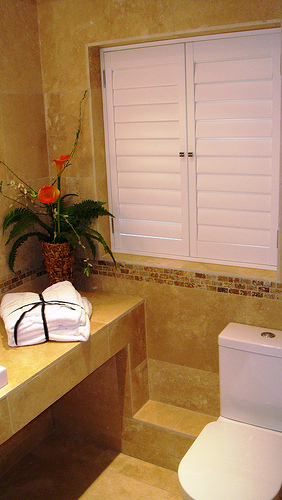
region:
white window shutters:
[95, 27, 281, 274]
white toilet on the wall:
[176, 319, 281, 499]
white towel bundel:
[1, 279, 99, 349]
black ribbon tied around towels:
[1, 280, 94, 347]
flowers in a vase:
[0, 150, 118, 300]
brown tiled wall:
[1, 0, 280, 193]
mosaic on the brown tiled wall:
[2, 252, 281, 322]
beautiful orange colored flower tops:
[36, 154, 73, 207]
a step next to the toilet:
[131, 391, 281, 498]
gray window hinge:
[99, 67, 110, 90]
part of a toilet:
[240, 457, 249, 465]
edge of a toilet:
[199, 444, 211, 460]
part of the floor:
[150, 397, 158, 413]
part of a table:
[46, 372, 57, 391]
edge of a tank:
[228, 357, 233, 365]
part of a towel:
[77, 330, 81, 338]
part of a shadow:
[86, 459, 98, 469]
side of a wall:
[163, 365, 172, 374]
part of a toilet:
[208, 444, 221, 457]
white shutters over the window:
[210, 108, 270, 188]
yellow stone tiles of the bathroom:
[81, 457, 135, 495]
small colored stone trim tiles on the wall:
[153, 272, 245, 293]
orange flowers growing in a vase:
[5, 164, 93, 283]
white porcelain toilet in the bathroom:
[176, 314, 273, 499]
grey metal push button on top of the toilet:
[257, 326, 275, 342]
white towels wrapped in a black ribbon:
[5, 281, 96, 341]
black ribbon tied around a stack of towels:
[32, 283, 58, 347]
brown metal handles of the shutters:
[178, 147, 200, 163]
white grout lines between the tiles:
[101, 325, 116, 359]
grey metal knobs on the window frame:
[174, 147, 201, 162]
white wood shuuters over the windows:
[208, 82, 260, 231]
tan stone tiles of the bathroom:
[94, 436, 162, 491]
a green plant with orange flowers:
[8, 160, 93, 286]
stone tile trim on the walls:
[138, 265, 262, 302]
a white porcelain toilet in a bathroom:
[176, 319, 281, 498]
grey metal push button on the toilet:
[258, 328, 276, 341]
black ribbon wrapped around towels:
[29, 287, 58, 346]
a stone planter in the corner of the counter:
[37, 239, 85, 289]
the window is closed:
[108, 40, 281, 262]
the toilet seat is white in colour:
[181, 416, 274, 494]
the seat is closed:
[189, 413, 281, 498]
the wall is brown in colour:
[63, 377, 179, 493]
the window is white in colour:
[96, 55, 278, 270]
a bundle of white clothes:
[3, 275, 98, 351]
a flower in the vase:
[2, 106, 95, 272]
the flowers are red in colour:
[20, 144, 109, 287]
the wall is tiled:
[23, 349, 77, 397]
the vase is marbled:
[40, 245, 81, 271]